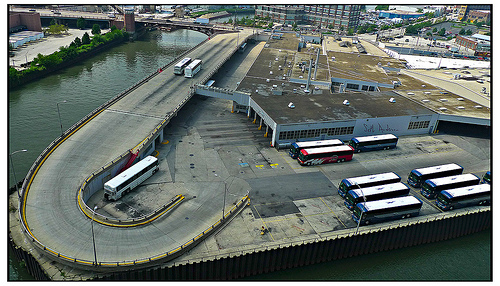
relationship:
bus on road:
[184, 59, 203, 78] [20, 27, 258, 269]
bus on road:
[404, 161, 466, 192] [28, 10, 483, 257]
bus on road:
[423, 170, 483, 204] [28, 10, 483, 257]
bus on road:
[182, 56, 204, 80] [28, 10, 483, 257]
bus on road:
[103, 152, 158, 199] [28, 10, 483, 257]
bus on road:
[347, 131, 398, 152] [28, 10, 483, 257]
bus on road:
[103, 152, 158, 199] [34, 34, 249, 258]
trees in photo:
[6, 20, 127, 86] [0, 8, 490, 280]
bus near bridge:
[103, 152, 158, 199] [12, 29, 252, 267]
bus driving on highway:
[174, 48, 185, 73] [20, 25, 419, 261]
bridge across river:
[7, 5, 242, 34] [6, 28, 216, 189]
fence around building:
[8, 177, 490, 280] [245, 89, 492, 150]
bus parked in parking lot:
[293, 140, 353, 168] [213, 156, 483, 213]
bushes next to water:
[11, 0, 133, 89] [93, 64, 114, 74]